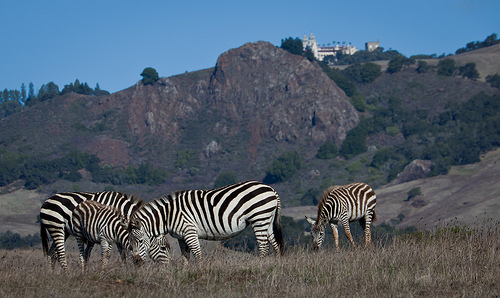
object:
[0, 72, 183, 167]
boulders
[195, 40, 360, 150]
boulder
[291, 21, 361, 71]
building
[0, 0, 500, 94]
sky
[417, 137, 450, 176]
bushes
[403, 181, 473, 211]
dirt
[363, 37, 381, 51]
building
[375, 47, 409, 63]
bushes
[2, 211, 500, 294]
grass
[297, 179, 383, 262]
zebra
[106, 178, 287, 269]
zebra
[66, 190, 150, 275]
zebra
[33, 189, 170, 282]
zebra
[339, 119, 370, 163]
bush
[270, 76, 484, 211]
hill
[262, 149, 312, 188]
bush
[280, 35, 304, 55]
bush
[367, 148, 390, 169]
bush